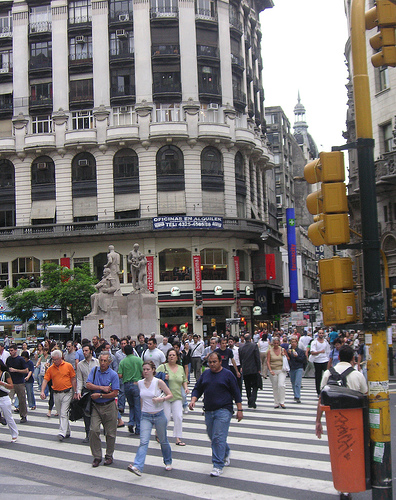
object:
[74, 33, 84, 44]
air conditioner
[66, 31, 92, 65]
window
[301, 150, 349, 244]
light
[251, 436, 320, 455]
white lines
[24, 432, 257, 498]
road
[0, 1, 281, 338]
building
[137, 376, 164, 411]
shirt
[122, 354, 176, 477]
woman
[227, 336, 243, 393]
man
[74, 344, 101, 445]
people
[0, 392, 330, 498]
crosswalk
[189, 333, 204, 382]
man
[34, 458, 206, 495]
white lines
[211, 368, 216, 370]
chin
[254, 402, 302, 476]
strips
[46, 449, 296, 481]
street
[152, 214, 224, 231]
sign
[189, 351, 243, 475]
man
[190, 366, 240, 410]
shirt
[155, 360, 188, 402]
shirt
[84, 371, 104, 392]
arm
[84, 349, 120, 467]
man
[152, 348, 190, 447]
people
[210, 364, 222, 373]
neck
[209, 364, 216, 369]
mouth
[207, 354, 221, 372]
head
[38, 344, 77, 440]
man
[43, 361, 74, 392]
orange shirt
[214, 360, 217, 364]
eye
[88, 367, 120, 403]
blue shirt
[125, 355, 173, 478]
people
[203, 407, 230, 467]
jeans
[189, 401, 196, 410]
hand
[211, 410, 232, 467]
leg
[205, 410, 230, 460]
leg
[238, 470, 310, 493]
lines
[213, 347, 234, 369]
shirt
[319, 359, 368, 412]
shirt